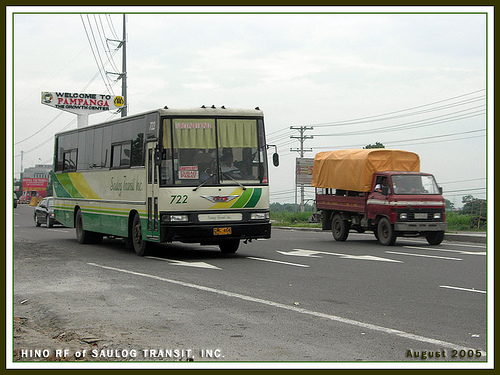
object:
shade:
[163, 117, 259, 149]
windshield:
[161, 117, 266, 186]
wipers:
[193, 169, 240, 191]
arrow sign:
[147, 255, 224, 270]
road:
[14, 201, 483, 374]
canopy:
[310, 148, 421, 194]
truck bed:
[315, 187, 369, 214]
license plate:
[213, 226, 232, 235]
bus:
[48, 104, 280, 257]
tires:
[131, 213, 157, 257]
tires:
[75, 208, 103, 244]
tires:
[217, 238, 241, 254]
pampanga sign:
[41, 92, 125, 112]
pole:
[300, 128, 305, 212]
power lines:
[311, 90, 484, 137]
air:
[143, 10, 498, 99]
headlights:
[399, 212, 408, 221]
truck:
[311, 147, 448, 246]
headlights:
[433, 213, 441, 219]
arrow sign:
[275, 248, 322, 258]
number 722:
[169, 194, 188, 204]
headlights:
[169, 214, 190, 222]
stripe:
[367, 198, 445, 207]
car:
[33, 196, 68, 227]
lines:
[87, 261, 485, 356]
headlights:
[250, 212, 266, 220]